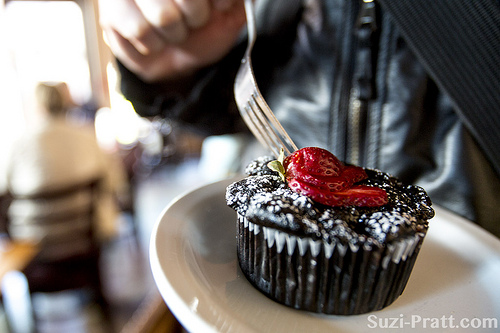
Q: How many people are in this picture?
A: Two.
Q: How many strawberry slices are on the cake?
A: Three.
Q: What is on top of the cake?
A: A strawberry.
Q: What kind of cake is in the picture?
A: A chocolate cake.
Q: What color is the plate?
A: White.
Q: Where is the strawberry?
A: On top of the cake.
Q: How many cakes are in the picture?
A: One.